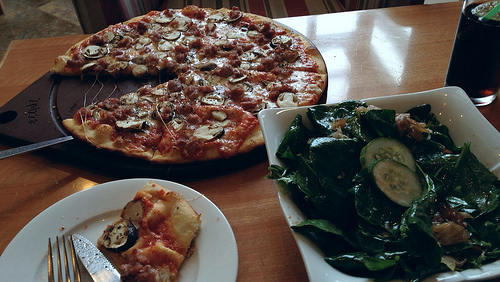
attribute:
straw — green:
[476, 0, 499, 19]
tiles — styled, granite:
[1, 0, 81, 46]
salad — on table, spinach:
[266, 90, 496, 276]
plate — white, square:
[5, 173, 243, 279]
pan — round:
[2, 4, 332, 196]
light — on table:
[278, 10, 421, 110]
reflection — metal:
[324, 19, 405, 91]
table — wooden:
[332, 30, 409, 80]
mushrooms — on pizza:
[118, 107, 154, 133]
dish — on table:
[3, 177, 241, 280]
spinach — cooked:
[317, 139, 352, 198]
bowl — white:
[417, 68, 474, 117]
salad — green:
[307, 101, 494, 266]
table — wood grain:
[288, 11, 410, 76]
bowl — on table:
[255, 57, 499, 279]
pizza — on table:
[39, 16, 319, 159]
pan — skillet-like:
[30, 73, 163, 105]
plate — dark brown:
[1, 7, 329, 177]